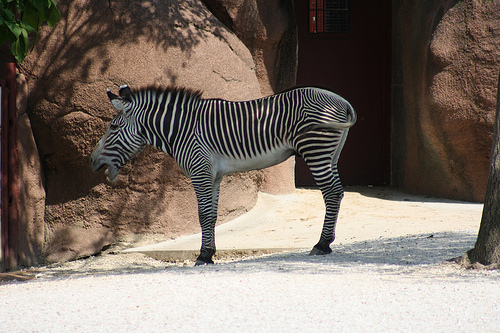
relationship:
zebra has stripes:
[92, 86, 354, 263] [173, 106, 321, 147]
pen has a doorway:
[1, 1, 498, 297] [285, 1, 392, 188]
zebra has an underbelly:
[92, 86, 354, 263] [219, 138, 287, 171]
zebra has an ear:
[92, 86, 354, 263] [103, 84, 127, 113]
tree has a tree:
[462, 149, 499, 268] [475, 149, 499, 264]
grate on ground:
[151, 243, 255, 270] [1, 188, 495, 333]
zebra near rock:
[92, 86, 354, 263] [391, 2, 499, 199]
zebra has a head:
[92, 86, 354, 263] [90, 83, 151, 178]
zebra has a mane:
[92, 86, 354, 263] [120, 83, 194, 106]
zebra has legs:
[92, 86, 354, 263] [187, 172, 227, 264]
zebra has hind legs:
[92, 86, 354, 263] [301, 143, 345, 256]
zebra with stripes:
[92, 86, 354, 263] [173, 106, 321, 147]